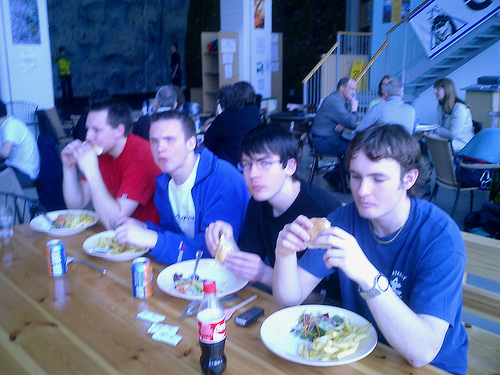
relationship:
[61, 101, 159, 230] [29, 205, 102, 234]
guy eating lunch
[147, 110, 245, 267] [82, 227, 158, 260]
guy eating lunch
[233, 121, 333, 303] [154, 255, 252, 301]
guy eating lunch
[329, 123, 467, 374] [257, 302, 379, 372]
guy eating lunch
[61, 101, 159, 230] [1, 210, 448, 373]
guy sitting at table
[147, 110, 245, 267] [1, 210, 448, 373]
guy sitting at table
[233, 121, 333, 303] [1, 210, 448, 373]
guy sitting at table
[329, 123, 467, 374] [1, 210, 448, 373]
guy sitting at table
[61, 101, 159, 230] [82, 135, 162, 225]
guy wearing t-shirt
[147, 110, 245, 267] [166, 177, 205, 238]
guy wearing t-shirt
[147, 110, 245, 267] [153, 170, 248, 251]
guy wearing jacket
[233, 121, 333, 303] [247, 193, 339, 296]
guy wearing t-shirt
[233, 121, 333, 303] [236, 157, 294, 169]
guy wearing glasses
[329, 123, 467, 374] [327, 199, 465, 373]
guy wearing t-shirt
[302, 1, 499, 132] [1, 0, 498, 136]
stairs are in background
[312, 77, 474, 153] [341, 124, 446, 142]
people sitting at table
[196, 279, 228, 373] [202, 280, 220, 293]
bottle has cap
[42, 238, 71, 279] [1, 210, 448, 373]
can on top of table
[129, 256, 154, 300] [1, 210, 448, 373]
can on top of table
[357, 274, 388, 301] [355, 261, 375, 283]
watch on wrist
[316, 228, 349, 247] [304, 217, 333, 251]
fingers holding bread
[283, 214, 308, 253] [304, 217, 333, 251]
fingers holding bread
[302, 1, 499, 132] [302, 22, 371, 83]
stairs have railing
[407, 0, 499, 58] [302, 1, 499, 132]
banner hangs from stairs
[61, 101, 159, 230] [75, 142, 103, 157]
guy eating sandwich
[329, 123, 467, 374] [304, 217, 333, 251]
guy eating sandwich